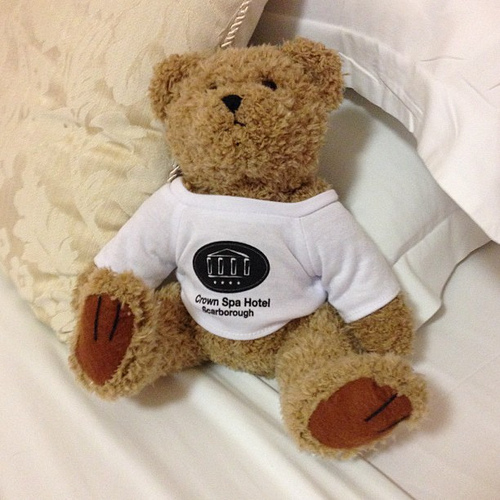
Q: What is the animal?
A: Bear.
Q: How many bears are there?
A: One.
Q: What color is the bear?
A: Brown.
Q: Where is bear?
A: On the bed.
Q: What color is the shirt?
A: Black and white.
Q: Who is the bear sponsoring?
A: Crown Spa Hotel.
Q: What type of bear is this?
A: Stuffed.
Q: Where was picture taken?
A: On a bedspread.